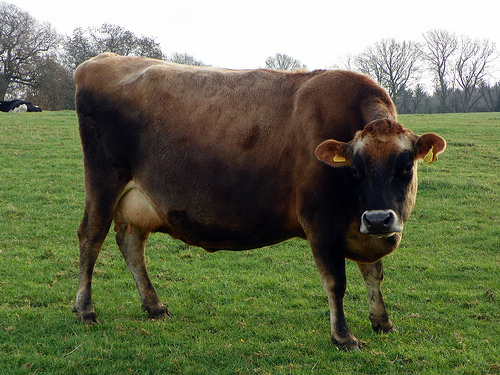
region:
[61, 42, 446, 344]
A very fat brown cow in a field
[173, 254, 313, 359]
Green grass below the cow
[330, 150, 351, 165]
A yellow tag on the cow's ear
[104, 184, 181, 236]
The udder of the brown cow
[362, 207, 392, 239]
A large black nose on the brown cow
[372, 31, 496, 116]
Brown trees in the distance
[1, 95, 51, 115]
A black and white cow lying down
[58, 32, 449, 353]
The large brown cow is standing still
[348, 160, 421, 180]
The cow's eyes are open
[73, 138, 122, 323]
the dark brown leg of a cow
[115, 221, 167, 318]
the dark brown leg of a cow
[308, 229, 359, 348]
the dark brown leg of a cow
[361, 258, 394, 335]
the dark brown leg of a cow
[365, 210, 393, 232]
the black large nose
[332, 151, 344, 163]
the yellow plastic tag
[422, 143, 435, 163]
the yellow plastic tag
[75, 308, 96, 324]
the hoof of a cow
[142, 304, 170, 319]
the hoof of a cow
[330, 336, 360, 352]
the hoof of a cow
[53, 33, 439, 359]
this is a cow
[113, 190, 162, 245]
the udder of a cow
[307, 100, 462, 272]
the head of a cow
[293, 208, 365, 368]
the foot of a cow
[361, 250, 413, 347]
the foot of a cow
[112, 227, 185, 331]
the foot of a cow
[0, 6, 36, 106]
this is a cow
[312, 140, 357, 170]
the yellow identification tag on the cows ear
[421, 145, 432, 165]
the ID tag on the cows ear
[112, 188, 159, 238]
the cows udder mammary gland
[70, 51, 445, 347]
a milk cow grazing in the field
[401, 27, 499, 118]
trees bordering the field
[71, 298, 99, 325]
the cows brown hooves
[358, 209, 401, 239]
the cows black nose area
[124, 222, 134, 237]
the pink nipple on the cows udder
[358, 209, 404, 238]
the cows white lips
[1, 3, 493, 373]
the scene takes place outdoors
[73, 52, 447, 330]
the cow is brown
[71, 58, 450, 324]
the animal is brown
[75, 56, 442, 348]
the cow is standing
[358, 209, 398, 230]
the cow has a black nose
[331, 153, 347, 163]
the cow has a tag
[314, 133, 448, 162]
the cow has ears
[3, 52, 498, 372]
the cow stands on the grass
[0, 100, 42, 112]
the cow is laying down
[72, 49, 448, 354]
cow is in the field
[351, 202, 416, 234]
white and black snout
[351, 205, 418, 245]
white and black snout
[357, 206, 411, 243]
white and black snout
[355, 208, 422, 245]
white and black snout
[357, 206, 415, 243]
white and black snout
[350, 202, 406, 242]
white and black snout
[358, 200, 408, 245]
white and black snout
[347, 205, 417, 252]
white and black snout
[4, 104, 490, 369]
a green pasture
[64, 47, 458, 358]
a fat brown cow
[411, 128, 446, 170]
yellow tag hanging from the cows ear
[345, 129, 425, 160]
white spots above the cows eyes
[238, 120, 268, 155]
small dark spot on the cows side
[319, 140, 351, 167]
yellow tag inside cows left ear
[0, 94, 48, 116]
black car sitting to the left